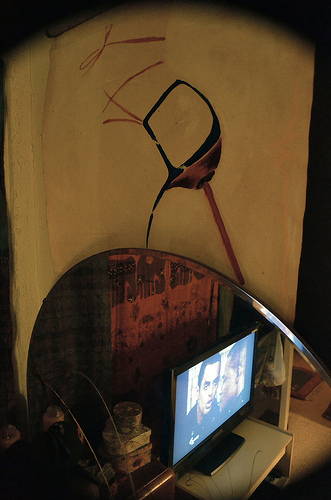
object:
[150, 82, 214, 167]
peice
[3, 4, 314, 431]
artwork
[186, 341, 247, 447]
two men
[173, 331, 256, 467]
tv screen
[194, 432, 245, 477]
tv stand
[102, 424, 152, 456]
gift box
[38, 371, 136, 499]
wires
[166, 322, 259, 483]
television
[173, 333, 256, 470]
shaped mirror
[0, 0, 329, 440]
wall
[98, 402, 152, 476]
box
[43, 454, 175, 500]
table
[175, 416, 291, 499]
table top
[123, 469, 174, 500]
round box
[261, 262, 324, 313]
part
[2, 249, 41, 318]
part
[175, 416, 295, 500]
table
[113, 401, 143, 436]
gift box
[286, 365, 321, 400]
mat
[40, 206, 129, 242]
part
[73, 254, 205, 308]
elephant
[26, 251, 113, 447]
fabric